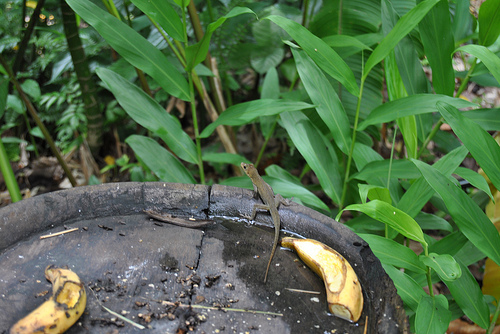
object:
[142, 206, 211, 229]
object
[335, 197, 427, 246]
leaves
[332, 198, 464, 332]
weeds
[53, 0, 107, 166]
trunk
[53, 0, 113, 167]
plant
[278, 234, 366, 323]
banana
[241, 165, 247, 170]
eye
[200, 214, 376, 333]
water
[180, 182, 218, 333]
crack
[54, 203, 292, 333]
stand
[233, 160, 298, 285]
lizard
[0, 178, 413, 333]
bird bath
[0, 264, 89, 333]
banana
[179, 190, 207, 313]
crack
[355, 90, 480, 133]
leaves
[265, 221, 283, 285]
tail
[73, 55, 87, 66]
stripes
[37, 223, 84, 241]
stick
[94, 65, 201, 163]
leaf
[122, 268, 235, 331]
pieces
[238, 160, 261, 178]
head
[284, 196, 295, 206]
foot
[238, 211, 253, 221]
foot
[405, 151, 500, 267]
leaf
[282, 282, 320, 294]
stick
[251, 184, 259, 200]
arms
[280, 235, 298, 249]
stem